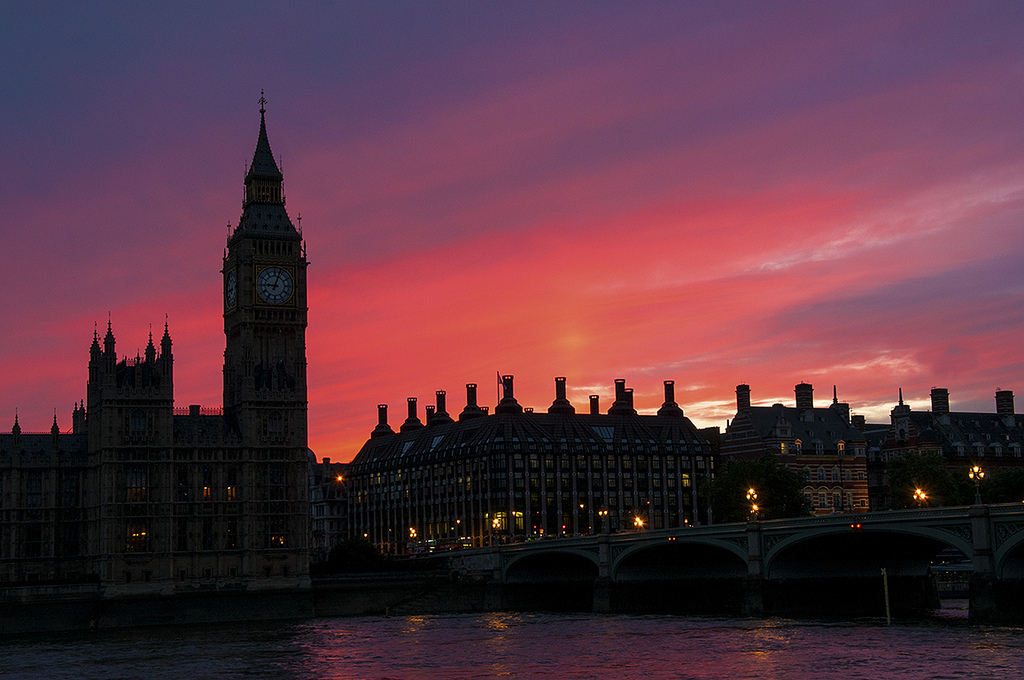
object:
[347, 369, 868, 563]
buildings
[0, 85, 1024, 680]
chimneys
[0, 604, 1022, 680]
river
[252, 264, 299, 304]
clock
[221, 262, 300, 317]
clock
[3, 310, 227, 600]
building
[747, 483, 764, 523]
light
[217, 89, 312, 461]
building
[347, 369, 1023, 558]
building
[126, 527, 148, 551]
light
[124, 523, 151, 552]
window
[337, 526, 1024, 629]
sign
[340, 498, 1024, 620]
bridge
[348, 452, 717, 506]
windows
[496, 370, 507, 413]
flag pole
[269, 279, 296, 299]
hands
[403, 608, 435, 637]
light reflection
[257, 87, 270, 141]
top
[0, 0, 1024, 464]
sky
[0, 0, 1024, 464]
cloud area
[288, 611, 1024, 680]
reflection